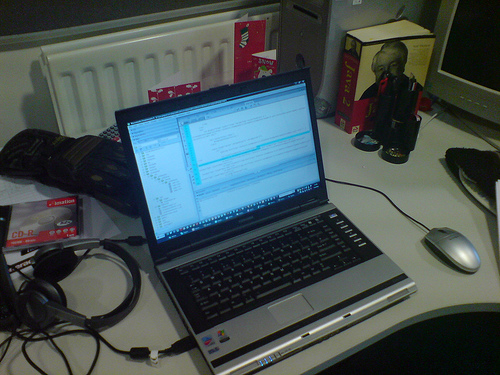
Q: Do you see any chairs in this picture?
A: No, there are no chairs.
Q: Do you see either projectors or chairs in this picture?
A: No, there are no chairs or projectors.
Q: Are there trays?
A: No, there are no trays.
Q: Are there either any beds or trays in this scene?
A: No, there are no trays or beds.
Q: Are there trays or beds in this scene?
A: No, there are no trays or beds.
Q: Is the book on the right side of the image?
A: Yes, the book is on the right of the image.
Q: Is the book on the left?
A: No, the book is on the right of the image.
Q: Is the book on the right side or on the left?
A: The book is on the right of the image.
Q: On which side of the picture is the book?
A: The book is on the right of the image.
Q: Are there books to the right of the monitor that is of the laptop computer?
A: Yes, there is a book to the right of the monitor.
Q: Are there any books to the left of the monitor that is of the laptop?
A: No, the book is to the right of the monitor.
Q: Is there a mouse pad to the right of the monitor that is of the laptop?
A: No, there is a book to the right of the monitor.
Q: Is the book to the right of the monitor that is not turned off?
A: Yes, the book is to the right of the monitor.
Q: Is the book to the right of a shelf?
A: No, the book is to the right of the monitor.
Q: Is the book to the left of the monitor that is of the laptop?
A: No, the book is to the right of the monitor.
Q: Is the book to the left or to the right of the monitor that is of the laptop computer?
A: The book is to the right of the monitor.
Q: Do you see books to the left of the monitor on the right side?
A: Yes, there is a book to the left of the monitor.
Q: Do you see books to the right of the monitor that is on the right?
A: No, the book is to the left of the monitor.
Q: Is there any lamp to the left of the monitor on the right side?
A: No, there is a book to the left of the monitor.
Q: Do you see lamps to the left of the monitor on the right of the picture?
A: No, there is a book to the left of the monitor.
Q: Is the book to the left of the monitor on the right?
A: Yes, the book is to the left of the monitor.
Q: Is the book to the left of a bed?
A: No, the book is to the left of the monitor.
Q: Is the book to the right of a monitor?
A: No, the book is to the left of a monitor.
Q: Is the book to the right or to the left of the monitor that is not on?
A: The book is to the left of the monitor.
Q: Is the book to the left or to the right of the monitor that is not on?
A: The book is to the left of the monitor.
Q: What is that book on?
A: The book is on the table.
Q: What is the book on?
A: The book is on the table.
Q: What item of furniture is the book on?
A: The book is on the table.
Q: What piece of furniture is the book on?
A: The book is on the table.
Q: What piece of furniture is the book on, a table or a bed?
A: The book is on a table.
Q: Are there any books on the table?
A: Yes, there is a book on the table.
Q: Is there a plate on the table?
A: No, there is a book on the table.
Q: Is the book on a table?
A: Yes, the book is on a table.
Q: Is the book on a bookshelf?
A: No, the book is on a table.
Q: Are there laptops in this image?
A: Yes, there is a laptop.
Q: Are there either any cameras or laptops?
A: Yes, there is a laptop.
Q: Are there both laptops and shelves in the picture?
A: No, there is a laptop but no shelves.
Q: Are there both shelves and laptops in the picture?
A: No, there is a laptop but no shelves.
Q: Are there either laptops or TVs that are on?
A: Yes, the laptop is on.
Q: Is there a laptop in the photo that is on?
A: Yes, there is a laptop that is on.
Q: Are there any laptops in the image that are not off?
A: Yes, there is a laptop that is on.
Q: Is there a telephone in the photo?
A: No, there are no phones.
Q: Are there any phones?
A: No, there are no phones.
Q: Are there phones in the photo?
A: No, there are no phones.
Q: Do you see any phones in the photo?
A: No, there are no phones.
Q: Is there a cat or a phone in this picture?
A: No, there are no phones or cats.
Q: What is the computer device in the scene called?
A: The device is a laptop.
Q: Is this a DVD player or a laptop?
A: This is a laptop.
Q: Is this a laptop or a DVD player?
A: This is a laptop.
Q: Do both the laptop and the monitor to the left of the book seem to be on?
A: Yes, both the laptop and the monitor are on.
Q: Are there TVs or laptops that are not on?
A: No, there is a laptop but it is on.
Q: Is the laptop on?
A: Yes, the laptop is on.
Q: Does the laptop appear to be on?
A: Yes, the laptop is on.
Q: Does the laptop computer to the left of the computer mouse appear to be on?
A: Yes, the laptop computer is on.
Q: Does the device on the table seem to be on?
A: Yes, the laptop computer is on.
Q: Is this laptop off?
A: No, the laptop is on.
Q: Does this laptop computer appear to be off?
A: No, the laptop computer is on.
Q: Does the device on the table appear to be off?
A: No, the laptop computer is on.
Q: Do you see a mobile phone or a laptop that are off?
A: No, there is a laptop but it is on.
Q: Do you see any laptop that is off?
A: No, there is a laptop but it is on.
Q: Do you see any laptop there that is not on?
A: No, there is a laptop but it is on.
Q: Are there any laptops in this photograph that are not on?
A: No, there is a laptop but it is on.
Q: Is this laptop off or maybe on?
A: The laptop is on.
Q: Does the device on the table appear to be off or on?
A: The laptop is on.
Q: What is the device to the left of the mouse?
A: The device is a laptop.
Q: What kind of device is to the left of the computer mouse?
A: The device is a laptop.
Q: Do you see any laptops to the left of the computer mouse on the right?
A: Yes, there is a laptop to the left of the computer mouse.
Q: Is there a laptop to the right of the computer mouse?
A: No, the laptop is to the left of the computer mouse.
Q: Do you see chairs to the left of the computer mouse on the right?
A: No, there is a laptop to the left of the computer mouse.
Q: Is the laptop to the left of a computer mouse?
A: Yes, the laptop is to the left of a computer mouse.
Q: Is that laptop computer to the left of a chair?
A: No, the laptop computer is to the left of a computer mouse.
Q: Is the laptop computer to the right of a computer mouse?
A: No, the laptop computer is to the left of a computer mouse.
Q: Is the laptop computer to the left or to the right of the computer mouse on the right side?
A: The laptop computer is to the left of the mouse.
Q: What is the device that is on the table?
A: The device is a laptop.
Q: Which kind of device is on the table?
A: The device is a laptop.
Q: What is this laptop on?
A: The laptop is on the table.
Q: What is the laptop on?
A: The laptop is on the table.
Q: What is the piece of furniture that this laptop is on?
A: The piece of furniture is a table.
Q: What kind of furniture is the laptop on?
A: The laptop is on the table.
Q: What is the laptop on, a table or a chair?
A: The laptop is on a table.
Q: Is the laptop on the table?
A: Yes, the laptop is on the table.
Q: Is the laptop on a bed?
A: No, the laptop is on the table.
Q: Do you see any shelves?
A: No, there are no shelves.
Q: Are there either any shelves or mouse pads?
A: No, there are no shelves or mouse pads.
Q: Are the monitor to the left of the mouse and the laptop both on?
A: Yes, both the monitor and the laptop are on.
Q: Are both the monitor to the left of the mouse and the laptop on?
A: Yes, both the monitor and the laptop are on.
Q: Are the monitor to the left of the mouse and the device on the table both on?
A: Yes, both the monitor and the laptop are on.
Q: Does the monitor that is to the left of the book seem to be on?
A: Yes, the monitor is on.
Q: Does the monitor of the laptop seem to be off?
A: No, the monitor is on.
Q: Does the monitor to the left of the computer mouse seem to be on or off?
A: The monitor is on.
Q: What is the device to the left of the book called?
A: The device is a monitor.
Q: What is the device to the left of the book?
A: The device is a monitor.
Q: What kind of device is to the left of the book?
A: The device is a monitor.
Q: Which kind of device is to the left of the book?
A: The device is a monitor.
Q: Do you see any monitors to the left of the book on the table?
A: Yes, there is a monitor to the left of the book.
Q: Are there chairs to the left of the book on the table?
A: No, there is a monitor to the left of the book.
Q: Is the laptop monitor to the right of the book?
A: No, the monitor is to the left of the book.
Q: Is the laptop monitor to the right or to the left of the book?
A: The monitor is to the left of the book.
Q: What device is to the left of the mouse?
A: The device is a monitor.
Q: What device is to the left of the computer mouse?
A: The device is a monitor.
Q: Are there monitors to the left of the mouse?
A: Yes, there is a monitor to the left of the mouse.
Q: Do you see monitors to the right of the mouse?
A: No, the monitor is to the left of the mouse.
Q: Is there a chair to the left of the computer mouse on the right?
A: No, there is a monitor to the left of the computer mouse.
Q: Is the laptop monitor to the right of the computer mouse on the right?
A: No, the monitor is to the left of the computer mouse.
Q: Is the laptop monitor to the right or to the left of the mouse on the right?
A: The monitor is to the left of the mouse.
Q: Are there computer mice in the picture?
A: Yes, there is a computer mouse.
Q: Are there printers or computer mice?
A: Yes, there is a computer mouse.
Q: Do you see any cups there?
A: No, there are no cups.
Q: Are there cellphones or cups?
A: No, there are no cups or cellphones.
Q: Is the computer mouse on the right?
A: Yes, the computer mouse is on the right of the image.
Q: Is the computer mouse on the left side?
A: No, the computer mouse is on the right of the image.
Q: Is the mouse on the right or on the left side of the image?
A: The mouse is on the right of the image.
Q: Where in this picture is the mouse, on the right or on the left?
A: The mouse is on the right of the image.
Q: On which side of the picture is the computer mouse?
A: The computer mouse is on the right of the image.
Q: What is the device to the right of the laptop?
A: The device is a computer mouse.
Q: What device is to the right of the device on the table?
A: The device is a computer mouse.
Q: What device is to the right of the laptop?
A: The device is a computer mouse.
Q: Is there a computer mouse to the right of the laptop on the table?
A: Yes, there is a computer mouse to the right of the laptop computer.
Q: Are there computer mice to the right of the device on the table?
A: Yes, there is a computer mouse to the right of the laptop computer.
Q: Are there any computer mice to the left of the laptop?
A: No, the computer mouse is to the right of the laptop.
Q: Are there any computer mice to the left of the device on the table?
A: No, the computer mouse is to the right of the laptop.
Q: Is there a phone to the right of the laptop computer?
A: No, there is a computer mouse to the right of the laptop computer.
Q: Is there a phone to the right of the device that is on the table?
A: No, there is a computer mouse to the right of the laptop computer.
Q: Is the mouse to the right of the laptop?
A: Yes, the mouse is to the right of the laptop.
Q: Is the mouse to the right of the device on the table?
A: Yes, the mouse is to the right of the laptop.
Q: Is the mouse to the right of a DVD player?
A: No, the mouse is to the right of the laptop.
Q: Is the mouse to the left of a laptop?
A: No, the mouse is to the right of a laptop.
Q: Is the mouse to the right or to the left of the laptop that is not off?
A: The mouse is to the right of the laptop computer.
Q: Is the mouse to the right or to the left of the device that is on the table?
A: The mouse is to the right of the laptop computer.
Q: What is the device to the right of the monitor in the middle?
A: The device is a computer mouse.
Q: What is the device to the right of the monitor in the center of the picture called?
A: The device is a computer mouse.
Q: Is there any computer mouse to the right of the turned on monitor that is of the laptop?
A: Yes, there is a computer mouse to the right of the monitor.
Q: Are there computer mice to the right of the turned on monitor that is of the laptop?
A: Yes, there is a computer mouse to the right of the monitor.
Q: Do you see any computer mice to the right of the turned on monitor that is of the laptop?
A: Yes, there is a computer mouse to the right of the monitor.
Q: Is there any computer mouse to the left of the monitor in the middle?
A: No, the computer mouse is to the right of the monitor.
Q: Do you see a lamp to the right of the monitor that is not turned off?
A: No, there is a computer mouse to the right of the monitor.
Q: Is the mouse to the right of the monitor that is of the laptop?
A: Yes, the mouse is to the right of the monitor.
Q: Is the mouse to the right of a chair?
A: No, the mouse is to the right of the monitor.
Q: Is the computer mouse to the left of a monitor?
A: No, the computer mouse is to the right of a monitor.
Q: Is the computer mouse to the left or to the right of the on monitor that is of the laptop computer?
A: The computer mouse is to the right of the monitor.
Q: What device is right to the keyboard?
A: The device is a computer mouse.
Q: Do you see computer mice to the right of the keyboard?
A: Yes, there is a computer mouse to the right of the keyboard.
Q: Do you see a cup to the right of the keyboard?
A: No, there is a computer mouse to the right of the keyboard.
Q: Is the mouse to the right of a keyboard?
A: Yes, the mouse is to the right of a keyboard.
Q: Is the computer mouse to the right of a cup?
A: No, the computer mouse is to the right of a keyboard.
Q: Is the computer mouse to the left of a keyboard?
A: No, the computer mouse is to the right of a keyboard.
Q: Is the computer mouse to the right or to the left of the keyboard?
A: The computer mouse is to the right of the keyboard.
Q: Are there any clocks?
A: No, there are no clocks.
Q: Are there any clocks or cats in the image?
A: No, there are no clocks or cats.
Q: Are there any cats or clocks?
A: No, there are no clocks or cats.